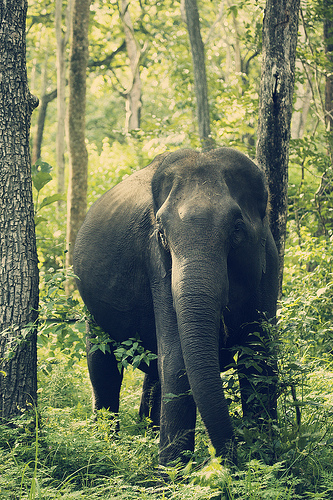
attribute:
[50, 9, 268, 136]
trees —  lot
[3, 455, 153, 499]
green bush — large 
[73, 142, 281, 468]
elephant — grey , looking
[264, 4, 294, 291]
tree — large 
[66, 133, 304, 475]
grey elephant — large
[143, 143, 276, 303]
head —  elephant's,  large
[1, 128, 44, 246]
trunk — rough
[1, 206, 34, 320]
tree — brown 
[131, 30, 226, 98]
leaves — green 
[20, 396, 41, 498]
grass — green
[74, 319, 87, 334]
leaf — green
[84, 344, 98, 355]
leaf — green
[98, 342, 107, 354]
leaf — green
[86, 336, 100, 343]
leaf — green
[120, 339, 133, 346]
leaf — green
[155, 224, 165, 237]
eye — open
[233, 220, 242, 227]
eye — open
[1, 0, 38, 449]
tree — large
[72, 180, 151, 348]
belly —  round,  big